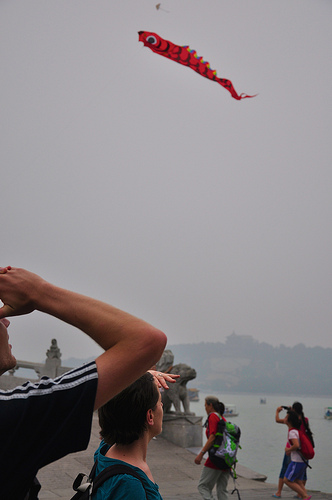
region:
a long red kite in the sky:
[132, 27, 251, 111]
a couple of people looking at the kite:
[0, 265, 184, 498]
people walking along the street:
[197, 396, 316, 497]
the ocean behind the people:
[194, 388, 331, 485]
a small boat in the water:
[217, 400, 239, 417]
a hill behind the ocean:
[179, 332, 329, 401]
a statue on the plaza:
[152, 354, 207, 456]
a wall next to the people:
[11, 333, 75, 385]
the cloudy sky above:
[1, 2, 331, 346]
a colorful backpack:
[199, 411, 240, 470]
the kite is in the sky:
[137, 27, 256, 100]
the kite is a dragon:
[137, 29, 256, 103]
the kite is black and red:
[138, 32, 258, 100]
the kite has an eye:
[138, 30, 258, 101]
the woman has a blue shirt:
[95, 439, 162, 497]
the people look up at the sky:
[0, 265, 181, 498]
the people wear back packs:
[71, 397, 313, 496]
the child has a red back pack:
[298, 429, 314, 459]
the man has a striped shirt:
[0, 358, 97, 496]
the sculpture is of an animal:
[162, 363, 196, 414]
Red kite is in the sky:
[117, 19, 256, 120]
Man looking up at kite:
[0, 248, 175, 425]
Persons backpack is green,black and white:
[210, 412, 249, 469]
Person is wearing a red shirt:
[191, 410, 231, 474]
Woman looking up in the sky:
[106, 370, 217, 493]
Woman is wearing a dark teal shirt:
[74, 432, 186, 498]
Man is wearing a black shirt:
[0, 363, 135, 497]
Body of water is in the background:
[200, 386, 328, 472]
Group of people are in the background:
[196, 384, 331, 477]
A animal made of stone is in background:
[159, 359, 207, 426]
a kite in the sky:
[87, 17, 283, 104]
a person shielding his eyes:
[72, 359, 187, 499]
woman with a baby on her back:
[184, 389, 244, 499]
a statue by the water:
[147, 336, 204, 449]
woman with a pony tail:
[184, 387, 232, 439]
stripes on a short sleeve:
[0, 343, 108, 470]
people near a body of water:
[138, 362, 331, 499]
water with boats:
[158, 382, 328, 498]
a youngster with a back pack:
[274, 407, 319, 498]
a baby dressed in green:
[209, 416, 248, 484]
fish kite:
[132, 26, 260, 105]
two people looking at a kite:
[4, 244, 188, 498]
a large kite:
[104, 7, 271, 121]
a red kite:
[116, 25, 278, 110]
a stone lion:
[132, 346, 209, 421]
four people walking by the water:
[191, 396, 325, 497]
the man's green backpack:
[196, 392, 246, 498]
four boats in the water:
[174, 378, 327, 426]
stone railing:
[1, 344, 209, 423]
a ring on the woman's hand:
[143, 363, 179, 392]